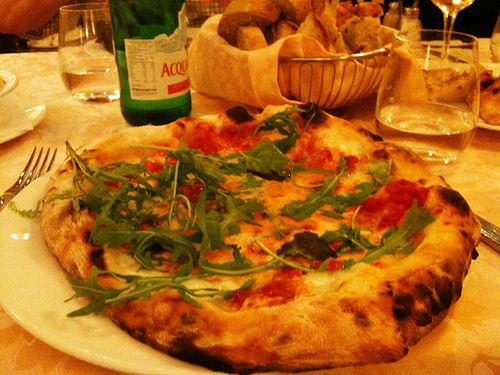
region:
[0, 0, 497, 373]
food sitting on table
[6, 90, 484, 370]
pizza hanging off plate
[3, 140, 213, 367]
dinner plate is white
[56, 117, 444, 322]
green vegetable on top pizza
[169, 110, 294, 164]
red sauce on pizza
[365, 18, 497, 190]
glass next to pizza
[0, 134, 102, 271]
fork next to plate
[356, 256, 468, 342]
pizza crust has brown spot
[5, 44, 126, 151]
tablecloth has floral print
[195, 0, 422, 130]
basket is made of metal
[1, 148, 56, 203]
a silver fork on the table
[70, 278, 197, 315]
a piece of green lettuce on the pizza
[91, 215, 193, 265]
a piece of green lettuce on the pizza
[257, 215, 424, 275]
a piece of green lettuce on the pizza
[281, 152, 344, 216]
a piece of green lettuce on the pizza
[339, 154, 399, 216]
a piece of green lettuce on the pizza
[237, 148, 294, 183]
a piece of green lettuce on the pizza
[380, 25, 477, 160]
a clear round short glass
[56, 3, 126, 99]
a clear round short glass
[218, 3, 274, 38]
a piece of sliced bread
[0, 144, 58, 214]
gray metal fork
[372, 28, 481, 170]
cup of water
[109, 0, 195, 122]
green bottle on the table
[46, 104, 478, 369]
vegetable pizza on white plate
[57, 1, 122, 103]
cup of water next to green bottle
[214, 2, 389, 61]
bread into gray basket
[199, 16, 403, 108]
gray metal basket where bread is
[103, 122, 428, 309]
melted cheese on pizza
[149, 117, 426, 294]
sliced red tomatoes on pizza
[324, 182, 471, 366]
toast borders of pizza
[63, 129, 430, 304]
The green garnish on the pizza.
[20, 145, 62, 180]
The points on the fork.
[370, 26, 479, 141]
The glass cup on the table.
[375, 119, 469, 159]
The liquid in the glass cup.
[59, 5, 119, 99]
The glass cup next to the green bottle.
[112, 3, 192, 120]
The green bottle on the table.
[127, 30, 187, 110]
The white label on the green bottle.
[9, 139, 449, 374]
The plate the pizza is on.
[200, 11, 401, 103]
The bowl of bread in the center of the table.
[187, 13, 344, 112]
The cloth under the bread in the bowl.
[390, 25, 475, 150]
glass of water on table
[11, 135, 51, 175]
fork on a table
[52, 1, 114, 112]
glass on a table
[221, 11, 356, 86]
bread in a basket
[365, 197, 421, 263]
basil on a pizza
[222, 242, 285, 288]
basil on a pizza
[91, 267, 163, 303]
basil on a pizza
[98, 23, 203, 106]
bottle on a table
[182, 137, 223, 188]
basil on a pizza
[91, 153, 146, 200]
basil on a pizza